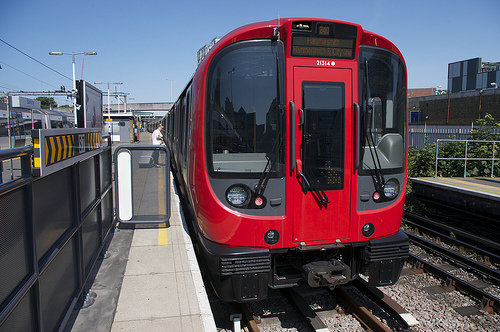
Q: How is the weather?
A: It is cloudless.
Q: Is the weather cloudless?
A: Yes, it is cloudless.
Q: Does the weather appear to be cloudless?
A: Yes, it is cloudless.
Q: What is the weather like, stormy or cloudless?
A: It is cloudless.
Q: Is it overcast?
A: No, it is cloudless.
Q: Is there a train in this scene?
A: Yes, there is a train.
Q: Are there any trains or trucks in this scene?
A: Yes, there is a train.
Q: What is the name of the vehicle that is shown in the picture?
A: The vehicle is a train.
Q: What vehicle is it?
A: The vehicle is a train.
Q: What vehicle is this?
A: This is a train.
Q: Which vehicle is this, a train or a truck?
A: This is a train.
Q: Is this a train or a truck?
A: This is a train.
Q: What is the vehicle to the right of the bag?
A: The vehicle is a train.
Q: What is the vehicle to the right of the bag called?
A: The vehicle is a train.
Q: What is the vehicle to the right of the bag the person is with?
A: The vehicle is a train.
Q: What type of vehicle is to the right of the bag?
A: The vehicle is a train.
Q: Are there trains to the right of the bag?
A: Yes, there is a train to the right of the bag.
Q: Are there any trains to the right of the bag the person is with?
A: Yes, there is a train to the right of the bag.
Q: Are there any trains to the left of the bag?
A: No, the train is to the right of the bag.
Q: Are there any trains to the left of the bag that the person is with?
A: No, the train is to the right of the bag.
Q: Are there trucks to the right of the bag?
A: No, there is a train to the right of the bag.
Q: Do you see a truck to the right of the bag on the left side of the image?
A: No, there is a train to the right of the bag.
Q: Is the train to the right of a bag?
A: Yes, the train is to the right of a bag.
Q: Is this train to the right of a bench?
A: No, the train is to the right of a bag.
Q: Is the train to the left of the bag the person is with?
A: No, the train is to the right of the bag.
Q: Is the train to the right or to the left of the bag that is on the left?
A: The train is to the right of the bag.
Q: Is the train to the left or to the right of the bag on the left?
A: The train is to the right of the bag.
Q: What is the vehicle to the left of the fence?
A: The vehicle is a train.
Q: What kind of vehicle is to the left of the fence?
A: The vehicle is a train.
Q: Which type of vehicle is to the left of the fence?
A: The vehicle is a train.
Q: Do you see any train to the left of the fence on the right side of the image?
A: Yes, there is a train to the left of the fence.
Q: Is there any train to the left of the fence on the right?
A: Yes, there is a train to the left of the fence.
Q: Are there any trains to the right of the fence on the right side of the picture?
A: No, the train is to the left of the fence.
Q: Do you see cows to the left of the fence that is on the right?
A: No, there is a train to the left of the fence.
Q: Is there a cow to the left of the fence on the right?
A: No, there is a train to the left of the fence.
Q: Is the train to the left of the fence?
A: Yes, the train is to the left of the fence.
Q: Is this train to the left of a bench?
A: No, the train is to the left of the fence.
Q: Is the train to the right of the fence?
A: No, the train is to the left of the fence.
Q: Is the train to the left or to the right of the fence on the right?
A: The train is to the left of the fence.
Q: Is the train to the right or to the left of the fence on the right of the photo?
A: The train is to the left of the fence.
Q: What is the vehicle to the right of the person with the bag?
A: The vehicle is a train.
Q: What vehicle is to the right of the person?
A: The vehicle is a train.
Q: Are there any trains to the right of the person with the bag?
A: Yes, there is a train to the right of the person.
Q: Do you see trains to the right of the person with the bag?
A: Yes, there is a train to the right of the person.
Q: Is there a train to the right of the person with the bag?
A: Yes, there is a train to the right of the person.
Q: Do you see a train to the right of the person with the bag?
A: Yes, there is a train to the right of the person.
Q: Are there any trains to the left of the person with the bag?
A: No, the train is to the right of the person.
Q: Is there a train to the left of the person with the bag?
A: No, the train is to the right of the person.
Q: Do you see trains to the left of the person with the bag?
A: No, the train is to the right of the person.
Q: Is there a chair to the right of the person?
A: No, there is a train to the right of the person.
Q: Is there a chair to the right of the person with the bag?
A: No, there is a train to the right of the person.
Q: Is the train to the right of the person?
A: Yes, the train is to the right of the person.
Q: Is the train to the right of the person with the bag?
A: Yes, the train is to the right of the person.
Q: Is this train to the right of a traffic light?
A: No, the train is to the right of the person.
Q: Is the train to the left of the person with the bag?
A: No, the train is to the right of the person.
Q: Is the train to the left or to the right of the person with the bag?
A: The train is to the right of the person.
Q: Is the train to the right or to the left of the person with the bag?
A: The train is to the right of the person.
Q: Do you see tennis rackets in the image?
A: No, there are no tennis rackets.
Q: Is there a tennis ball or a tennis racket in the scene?
A: No, there are no rackets or tennis balls.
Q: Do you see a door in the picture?
A: Yes, there is a door.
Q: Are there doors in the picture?
A: Yes, there is a door.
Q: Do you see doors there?
A: Yes, there is a door.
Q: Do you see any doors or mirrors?
A: Yes, there is a door.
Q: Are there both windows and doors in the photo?
A: Yes, there are both a door and a window.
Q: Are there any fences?
A: Yes, there is a fence.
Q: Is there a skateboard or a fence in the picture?
A: Yes, there is a fence.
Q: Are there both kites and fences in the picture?
A: No, there is a fence but no kites.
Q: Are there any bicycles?
A: No, there are no bicycles.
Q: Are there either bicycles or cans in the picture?
A: No, there are no bicycles or cans.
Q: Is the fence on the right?
A: Yes, the fence is on the right of the image.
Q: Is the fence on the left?
A: No, the fence is on the right of the image.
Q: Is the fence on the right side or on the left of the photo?
A: The fence is on the right of the image.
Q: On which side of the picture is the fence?
A: The fence is on the right of the image.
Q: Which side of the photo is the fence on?
A: The fence is on the right of the image.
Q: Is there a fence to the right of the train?
A: Yes, there is a fence to the right of the train.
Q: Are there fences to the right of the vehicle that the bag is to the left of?
A: Yes, there is a fence to the right of the train.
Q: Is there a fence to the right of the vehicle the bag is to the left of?
A: Yes, there is a fence to the right of the train.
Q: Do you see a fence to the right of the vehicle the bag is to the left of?
A: Yes, there is a fence to the right of the train.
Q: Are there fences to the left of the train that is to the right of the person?
A: No, the fence is to the right of the train.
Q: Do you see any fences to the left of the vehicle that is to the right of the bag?
A: No, the fence is to the right of the train.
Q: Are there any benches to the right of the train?
A: No, there is a fence to the right of the train.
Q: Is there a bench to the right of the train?
A: No, there is a fence to the right of the train.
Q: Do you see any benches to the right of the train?
A: No, there is a fence to the right of the train.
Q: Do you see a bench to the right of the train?
A: No, there is a fence to the right of the train.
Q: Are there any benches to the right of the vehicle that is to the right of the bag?
A: No, there is a fence to the right of the train.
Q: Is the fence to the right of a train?
A: Yes, the fence is to the right of a train.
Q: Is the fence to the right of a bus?
A: No, the fence is to the right of a train.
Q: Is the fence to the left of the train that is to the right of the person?
A: No, the fence is to the right of the train.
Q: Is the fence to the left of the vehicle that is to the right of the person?
A: No, the fence is to the right of the train.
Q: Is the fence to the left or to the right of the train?
A: The fence is to the right of the train.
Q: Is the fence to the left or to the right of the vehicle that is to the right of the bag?
A: The fence is to the right of the train.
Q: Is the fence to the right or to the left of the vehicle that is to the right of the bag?
A: The fence is to the right of the train.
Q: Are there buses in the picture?
A: No, there are no buses.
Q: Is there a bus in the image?
A: No, there are no buses.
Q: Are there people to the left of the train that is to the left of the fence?
A: Yes, there is a person to the left of the train.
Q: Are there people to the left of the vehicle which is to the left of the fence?
A: Yes, there is a person to the left of the train.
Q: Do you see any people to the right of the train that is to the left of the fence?
A: No, the person is to the left of the train.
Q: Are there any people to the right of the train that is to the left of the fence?
A: No, the person is to the left of the train.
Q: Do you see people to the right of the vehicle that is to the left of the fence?
A: No, the person is to the left of the train.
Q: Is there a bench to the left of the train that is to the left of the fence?
A: No, there is a person to the left of the train.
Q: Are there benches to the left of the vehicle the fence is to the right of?
A: No, there is a person to the left of the train.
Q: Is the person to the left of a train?
A: Yes, the person is to the left of a train.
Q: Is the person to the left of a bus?
A: No, the person is to the left of a train.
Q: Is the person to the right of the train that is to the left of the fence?
A: No, the person is to the left of the train.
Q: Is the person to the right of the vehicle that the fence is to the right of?
A: No, the person is to the left of the train.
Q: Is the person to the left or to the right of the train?
A: The person is to the left of the train.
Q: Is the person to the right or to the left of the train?
A: The person is to the left of the train.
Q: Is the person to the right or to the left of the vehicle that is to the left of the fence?
A: The person is to the left of the train.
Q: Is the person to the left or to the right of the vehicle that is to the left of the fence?
A: The person is to the left of the train.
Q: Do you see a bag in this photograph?
A: Yes, there is a bag.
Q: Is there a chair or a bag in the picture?
A: Yes, there is a bag.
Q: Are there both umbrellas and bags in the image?
A: No, there is a bag but no umbrellas.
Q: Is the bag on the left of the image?
A: Yes, the bag is on the left of the image.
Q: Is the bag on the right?
A: No, the bag is on the left of the image.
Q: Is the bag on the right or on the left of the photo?
A: The bag is on the left of the image.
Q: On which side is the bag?
A: The bag is on the left of the image.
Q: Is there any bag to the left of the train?
A: Yes, there is a bag to the left of the train.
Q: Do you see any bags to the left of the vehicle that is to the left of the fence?
A: Yes, there is a bag to the left of the train.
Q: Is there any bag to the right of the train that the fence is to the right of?
A: No, the bag is to the left of the train.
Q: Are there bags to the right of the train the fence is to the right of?
A: No, the bag is to the left of the train.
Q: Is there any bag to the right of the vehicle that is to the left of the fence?
A: No, the bag is to the left of the train.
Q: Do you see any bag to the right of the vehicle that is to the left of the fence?
A: No, the bag is to the left of the train.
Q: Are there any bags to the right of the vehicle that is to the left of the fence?
A: No, the bag is to the left of the train.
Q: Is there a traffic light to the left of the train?
A: No, there is a bag to the left of the train.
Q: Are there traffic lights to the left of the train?
A: No, there is a bag to the left of the train.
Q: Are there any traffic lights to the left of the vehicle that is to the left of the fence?
A: No, there is a bag to the left of the train.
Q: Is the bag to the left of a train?
A: Yes, the bag is to the left of a train.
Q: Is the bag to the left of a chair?
A: No, the bag is to the left of a train.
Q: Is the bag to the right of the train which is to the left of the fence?
A: No, the bag is to the left of the train.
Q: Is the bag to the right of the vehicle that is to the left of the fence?
A: No, the bag is to the left of the train.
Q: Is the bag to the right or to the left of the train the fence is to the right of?
A: The bag is to the left of the train.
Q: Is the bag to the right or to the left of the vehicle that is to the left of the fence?
A: The bag is to the left of the train.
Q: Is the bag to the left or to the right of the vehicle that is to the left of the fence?
A: The bag is to the left of the train.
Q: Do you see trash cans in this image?
A: No, there are no trash cans.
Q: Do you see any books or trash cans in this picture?
A: No, there are no trash cans or books.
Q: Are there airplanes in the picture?
A: No, there are no airplanes.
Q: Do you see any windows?
A: Yes, there is a window.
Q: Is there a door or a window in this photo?
A: Yes, there is a window.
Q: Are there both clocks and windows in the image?
A: No, there is a window but no clocks.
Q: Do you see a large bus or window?
A: Yes, there is a large window.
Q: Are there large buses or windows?
A: Yes, there is a large window.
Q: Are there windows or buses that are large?
A: Yes, the window is large.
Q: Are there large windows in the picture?
A: Yes, there is a large window.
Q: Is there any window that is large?
A: Yes, there is a window that is large.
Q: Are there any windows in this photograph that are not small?
A: Yes, there is a large window.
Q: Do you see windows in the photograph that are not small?
A: Yes, there is a large window.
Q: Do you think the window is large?
A: Yes, the window is large.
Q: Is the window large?
A: Yes, the window is large.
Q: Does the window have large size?
A: Yes, the window is large.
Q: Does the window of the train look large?
A: Yes, the window is large.